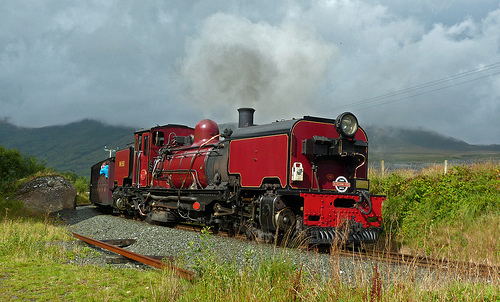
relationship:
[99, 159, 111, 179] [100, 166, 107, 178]
man wearing shirt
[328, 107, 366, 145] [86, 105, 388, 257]
light on train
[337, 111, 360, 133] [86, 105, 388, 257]
light on train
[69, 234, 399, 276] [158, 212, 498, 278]
gravel on tracks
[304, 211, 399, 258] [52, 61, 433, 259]
bumper of steam engine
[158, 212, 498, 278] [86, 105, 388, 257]
tracks in front of train